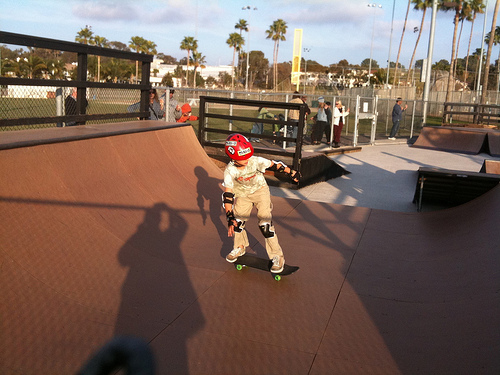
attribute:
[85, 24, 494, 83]
trees — palms, in background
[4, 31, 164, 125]
fence — brown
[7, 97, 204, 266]
ramp — short, brown, in park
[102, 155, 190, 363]
shadow — photographer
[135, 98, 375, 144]
people — spectators, grouped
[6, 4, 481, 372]
scene — skate park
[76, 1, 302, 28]
clouds — in sky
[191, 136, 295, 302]
skater — skateboarding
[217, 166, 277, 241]
safety gear — black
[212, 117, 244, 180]
helmet — red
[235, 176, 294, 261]
pants — khaki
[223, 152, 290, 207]
shirt — white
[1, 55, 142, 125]
railings — black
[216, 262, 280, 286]
wheels — green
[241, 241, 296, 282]
skateboard — black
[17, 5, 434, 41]
sky — cloudy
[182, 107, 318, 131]
grass — green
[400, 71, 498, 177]
skate ramp — in background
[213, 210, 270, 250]
knees — protected